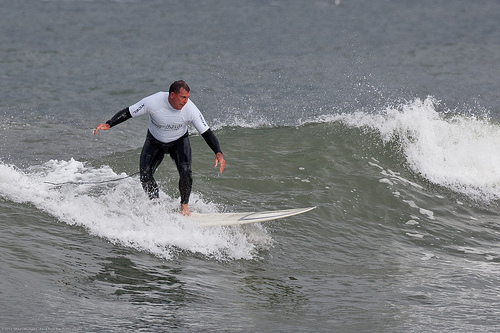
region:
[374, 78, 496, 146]
water in the air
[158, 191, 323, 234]
surfboard in the water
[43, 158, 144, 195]
surfboard leash attached to man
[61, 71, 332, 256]
man on a surfboard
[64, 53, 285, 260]
man in the water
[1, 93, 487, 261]
wave on the water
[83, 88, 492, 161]
crest of the wave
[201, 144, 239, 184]
hand of the man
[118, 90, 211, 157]
white shirt of the man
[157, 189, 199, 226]
man's foot on the surfboard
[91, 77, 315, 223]
man standing on surfboard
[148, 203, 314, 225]
white surfboard with rider on top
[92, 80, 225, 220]
surfer wearing black pants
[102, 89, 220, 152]
white shirt with black sleeves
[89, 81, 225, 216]
man wearing white shirt with black sleeves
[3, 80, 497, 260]
man riding wave on surfboard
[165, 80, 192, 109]
brown hair on head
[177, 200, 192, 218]
foot is in water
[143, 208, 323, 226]
white surfboard wtih logo on tip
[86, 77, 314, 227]
man riding white surfboard with logo on tip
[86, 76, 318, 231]
Man riding surfboard on wave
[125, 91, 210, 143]
White t shirt on man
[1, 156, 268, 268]
Wake in water created by surfboard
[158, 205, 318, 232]
White surfboard on the water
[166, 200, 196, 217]
Barefoot of a man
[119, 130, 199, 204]
Black wetsuit pants on man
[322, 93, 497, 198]
White water spray caused by wave breaking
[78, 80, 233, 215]
Man with arms extended for balance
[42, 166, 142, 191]
Tether line on man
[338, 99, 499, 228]
Crest of wave breaking toward shore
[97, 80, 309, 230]
the man is surfing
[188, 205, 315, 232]
the surf board is white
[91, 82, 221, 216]
the man is wearing a wet suit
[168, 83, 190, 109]
the man has short hair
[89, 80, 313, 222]
the man is on the water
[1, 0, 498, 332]
the scene takes place outdoors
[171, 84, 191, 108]
the man is looking down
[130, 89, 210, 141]
the man has a white top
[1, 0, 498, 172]
calmer section of the ocean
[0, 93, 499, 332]
medium sized wave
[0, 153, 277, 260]
disturbance of water caused by the wave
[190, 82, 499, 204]
disturbance of water caused by the wave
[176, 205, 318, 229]
white surfboard with blue markings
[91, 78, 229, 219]
middle aged male surfer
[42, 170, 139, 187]
black surfers lead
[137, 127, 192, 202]
black surfing leggings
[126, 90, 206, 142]
white surfing shirt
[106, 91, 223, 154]
black undershirt